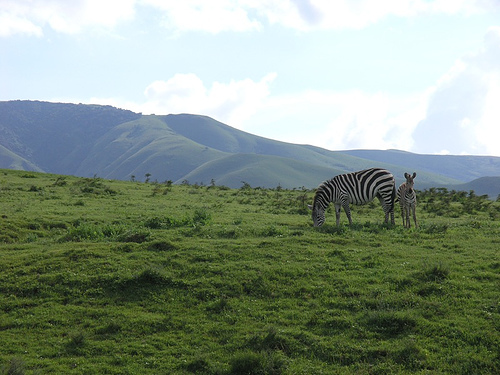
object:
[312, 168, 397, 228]
zebra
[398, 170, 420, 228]
zebra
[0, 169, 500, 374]
ground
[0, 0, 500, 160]
sky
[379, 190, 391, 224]
leg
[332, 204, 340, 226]
leg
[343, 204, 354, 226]
leg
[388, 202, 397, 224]
leg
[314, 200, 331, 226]
head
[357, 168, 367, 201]
stripes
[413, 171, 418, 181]
ear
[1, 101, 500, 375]
mountains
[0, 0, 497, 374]
background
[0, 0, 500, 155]
clouds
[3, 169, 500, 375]
grass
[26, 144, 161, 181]
valley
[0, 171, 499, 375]
bushes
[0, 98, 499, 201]
hills